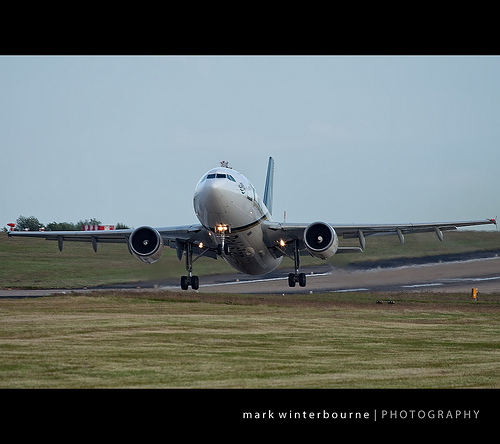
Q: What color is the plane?
A: White.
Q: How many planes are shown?
A: One.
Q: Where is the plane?
A: On runway.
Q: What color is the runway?
A: Gray.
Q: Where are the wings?
A: On plane.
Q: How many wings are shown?
A: Two.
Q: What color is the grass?
A: Green.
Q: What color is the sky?
A: Blue.